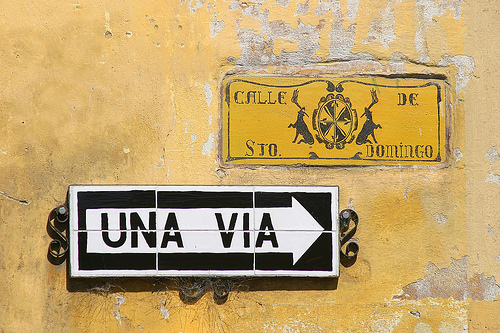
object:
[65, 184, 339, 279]
sign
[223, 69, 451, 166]
sign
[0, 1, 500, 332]
building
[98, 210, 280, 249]
una via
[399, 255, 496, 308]
concrete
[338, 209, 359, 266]
embellishment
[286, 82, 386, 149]
emblem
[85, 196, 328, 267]
arrow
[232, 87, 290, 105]
text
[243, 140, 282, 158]
text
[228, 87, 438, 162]
calle de sto domingo